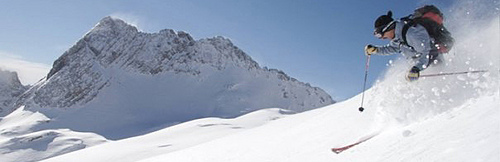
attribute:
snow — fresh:
[0, 24, 498, 160]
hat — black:
[382, 2, 397, 39]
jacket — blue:
[352, 11, 463, 98]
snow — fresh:
[162, 86, 299, 153]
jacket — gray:
[377, 20, 435, 68]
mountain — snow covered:
[12, 12, 335, 136]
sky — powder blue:
[286, 14, 327, 66]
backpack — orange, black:
[405, 3, 451, 45]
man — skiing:
[362, 2, 455, 87]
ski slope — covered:
[3, 10, 483, 156]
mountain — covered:
[7, 11, 333, 152]